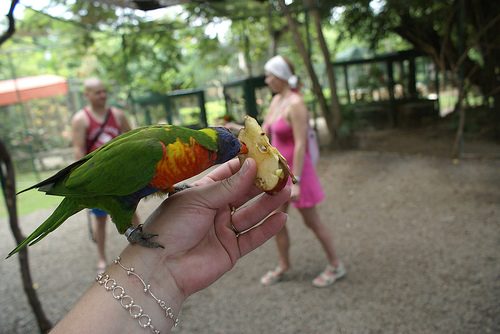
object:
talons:
[120, 225, 168, 248]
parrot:
[9, 112, 249, 257]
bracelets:
[111, 251, 186, 328]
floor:
[379, 173, 466, 303]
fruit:
[234, 114, 300, 196]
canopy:
[0, 73, 67, 105]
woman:
[248, 49, 349, 289]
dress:
[262, 89, 327, 211]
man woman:
[67, 57, 348, 281]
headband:
[263, 54, 297, 90]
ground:
[167, 137, 498, 329]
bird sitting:
[2, 107, 293, 290]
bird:
[28, 107, 299, 260]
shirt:
[83, 107, 120, 154]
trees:
[347, 0, 494, 118]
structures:
[328, 47, 441, 124]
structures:
[222, 68, 275, 125]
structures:
[130, 87, 208, 131]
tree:
[189, 1, 267, 122]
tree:
[265, 2, 351, 148]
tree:
[17, 0, 68, 188]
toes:
[258, 243, 389, 298]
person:
[258, 56, 347, 288]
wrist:
[81, 235, 182, 332]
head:
[213, 126, 248, 165]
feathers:
[20, 122, 216, 195]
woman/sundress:
[256, 49, 346, 289]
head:
[81, 75, 107, 109]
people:
[66, 76, 140, 282]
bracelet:
[90, 252, 179, 327]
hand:
[144, 154, 288, 304]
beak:
[238, 139, 251, 155]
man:
[70, 74, 142, 275]